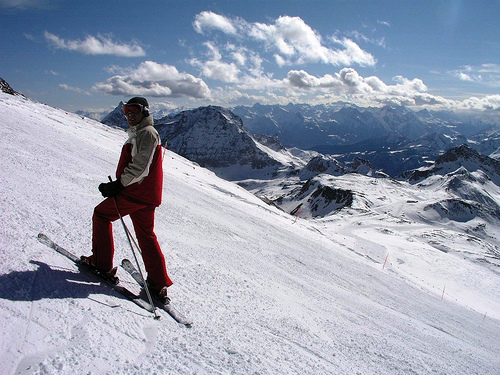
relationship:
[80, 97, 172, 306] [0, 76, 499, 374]
skier on a hill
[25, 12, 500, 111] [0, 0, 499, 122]
clouds in sky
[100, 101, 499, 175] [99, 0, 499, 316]
mountains in background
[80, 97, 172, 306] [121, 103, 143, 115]
skier wearing goggles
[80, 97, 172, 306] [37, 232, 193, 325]
skier on skis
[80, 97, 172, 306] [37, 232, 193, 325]
skier wearing skis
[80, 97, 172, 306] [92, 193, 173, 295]
skier wearing pants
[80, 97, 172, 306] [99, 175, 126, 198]
skier wearing gloves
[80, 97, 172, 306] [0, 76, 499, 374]
skier on hill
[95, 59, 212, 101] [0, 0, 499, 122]
cloud in sky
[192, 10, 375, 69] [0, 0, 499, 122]
cloud in sky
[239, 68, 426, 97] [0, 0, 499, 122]
cloud in sky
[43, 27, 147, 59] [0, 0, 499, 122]
cloud in sky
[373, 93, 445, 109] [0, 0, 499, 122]
cloud in sky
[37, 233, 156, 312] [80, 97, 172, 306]
ski on left of skier